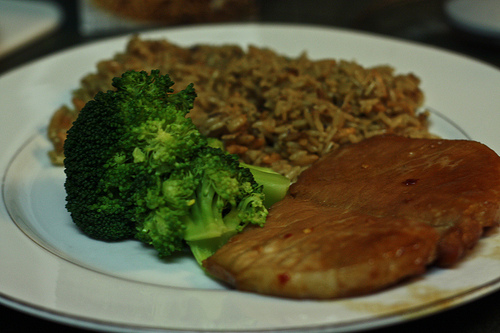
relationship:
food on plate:
[46, 34, 498, 304] [4, 23, 499, 329]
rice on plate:
[47, 33, 442, 183] [4, 23, 499, 329]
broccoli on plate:
[63, 68, 269, 265] [4, 23, 499, 329]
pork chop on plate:
[201, 132, 499, 300] [4, 23, 499, 329]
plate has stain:
[4, 23, 499, 329] [329, 286, 459, 322]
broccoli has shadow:
[63, 68, 269, 265] [128, 234, 152, 251]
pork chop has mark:
[201, 132, 499, 300] [278, 272, 290, 284]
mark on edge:
[278, 272, 290, 284] [220, 260, 362, 302]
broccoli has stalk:
[63, 68, 269, 265] [235, 158, 293, 208]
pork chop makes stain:
[201, 132, 499, 300] [329, 286, 459, 322]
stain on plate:
[329, 286, 459, 322] [4, 23, 499, 329]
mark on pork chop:
[278, 272, 290, 284] [201, 132, 499, 300]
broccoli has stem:
[63, 68, 269, 265] [235, 158, 293, 208]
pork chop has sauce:
[201, 132, 499, 300] [470, 218, 499, 260]